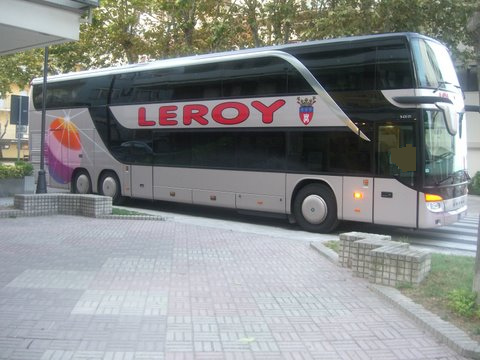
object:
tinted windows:
[138, 61, 298, 97]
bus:
[28, 33, 468, 228]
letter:
[180, 97, 212, 127]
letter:
[252, 94, 287, 128]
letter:
[156, 103, 180, 126]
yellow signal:
[352, 193, 363, 198]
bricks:
[294, 319, 317, 331]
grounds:
[403, 161, 417, 187]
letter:
[210, 101, 249, 125]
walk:
[178, 252, 461, 332]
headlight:
[435, 219, 444, 226]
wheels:
[67, 171, 92, 193]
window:
[377, 37, 418, 89]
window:
[461, 67, 477, 88]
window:
[10, 94, 29, 125]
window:
[376, 123, 416, 177]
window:
[424, 110, 467, 180]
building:
[455, 3, 478, 150]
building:
[0, 0, 96, 162]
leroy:
[136, 98, 284, 128]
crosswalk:
[387, 210, 478, 258]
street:
[0, 175, 478, 253]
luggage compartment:
[150, 164, 288, 218]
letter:
[138, 107, 155, 126]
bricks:
[350, 235, 398, 281]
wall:
[120, 72, 158, 125]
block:
[336, 230, 429, 287]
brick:
[411, 276, 418, 282]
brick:
[375, 251, 383, 258]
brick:
[373, 277, 379, 283]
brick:
[350, 271, 355, 276]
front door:
[371, 118, 419, 230]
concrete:
[318, 211, 427, 317]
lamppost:
[40, 40, 48, 190]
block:
[370, 242, 415, 286]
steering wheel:
[432, 153, 453, 162]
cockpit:
[381, 118, 420, 175]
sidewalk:
[5, 191, 464, 354]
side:
[30, 30, 414, 228]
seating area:
[340, 232, 434, 288]